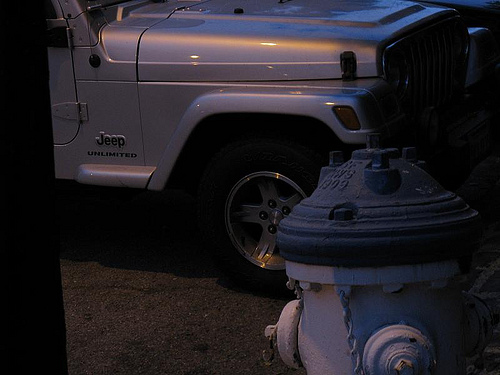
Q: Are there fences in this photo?
A: No, there are no fences.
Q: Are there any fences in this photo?
A: No, there are no fences.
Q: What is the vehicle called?
A: The vehicle is a jeep.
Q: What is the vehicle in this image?
A: The vehicle is a jeep.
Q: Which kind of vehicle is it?
A: The vehicle is a jeep.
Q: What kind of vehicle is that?
A: That is a jeep.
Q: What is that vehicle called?
A: That is a jeep.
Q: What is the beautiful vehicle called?
A: The vehicle is a jeep.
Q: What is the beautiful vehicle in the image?
A: The vehicle is a jeep.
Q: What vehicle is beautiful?
A: The vehicle is a jeep.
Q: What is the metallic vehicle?
A: The vehicle is a jeep.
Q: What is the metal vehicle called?
A: The vehicle is a jeep.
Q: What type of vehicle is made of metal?
A: The vehicle is a jeep.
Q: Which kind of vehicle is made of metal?
A: The vehicle is a jeep.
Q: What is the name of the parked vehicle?
A: The vehicle is a jeep.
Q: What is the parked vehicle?
A: The vehicle is a jeep.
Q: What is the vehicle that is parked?
A: The vehicle is a jeep.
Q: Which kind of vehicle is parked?
A: The vehicle is a jeep.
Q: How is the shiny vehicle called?
A: The vehicle is a jeep.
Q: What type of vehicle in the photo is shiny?
A: The vehicle is a jeep.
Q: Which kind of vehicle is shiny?
A: The vehicle is a jeep.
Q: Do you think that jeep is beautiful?
A: Yes, the jeep is beautiful.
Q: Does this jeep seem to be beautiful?
A: Yes, the jeep is beautiful.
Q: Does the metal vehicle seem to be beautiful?
A: Yes, the jeep is beautiful.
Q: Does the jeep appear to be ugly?
A: No, the jeep is beautiful.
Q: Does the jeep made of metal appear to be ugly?
A: No, the jeep is beautiful.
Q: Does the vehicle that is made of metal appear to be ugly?
A: No, the jeep is beautiful.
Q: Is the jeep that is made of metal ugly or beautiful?
A: The jeep is beautiful.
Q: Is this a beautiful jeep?
A: Yes, this is a beautiful jeep.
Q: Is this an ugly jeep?
A: No, this is a beautiful jeep.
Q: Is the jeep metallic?
A: Yes, the jeep is metallic.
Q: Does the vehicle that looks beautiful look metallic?
A: Yes, the jeep is metallic.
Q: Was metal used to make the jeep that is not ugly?
A: Yes, the jeep is made of metal.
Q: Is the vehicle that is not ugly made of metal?
A: Yes, the jeep is made of metal.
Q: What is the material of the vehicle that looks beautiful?
A: The jeep is made of metal.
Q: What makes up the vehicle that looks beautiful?
A: The jeep is made of metal.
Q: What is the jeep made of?
A: The jeep is made of metal.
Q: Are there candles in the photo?
A: No, there are no candles.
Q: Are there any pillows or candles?
A: No, there are no candles or pillows.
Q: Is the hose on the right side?
A: Yes, the hose is on the right of the image.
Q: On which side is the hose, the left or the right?
A: The hose is on the right of the image.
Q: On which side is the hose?
A: The hose is on the right of the image.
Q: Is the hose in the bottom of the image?
A: Yes, the hose is in the bottom of the image.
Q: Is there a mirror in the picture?
A: Yes, there is a mirror.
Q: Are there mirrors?
A: Yes, there is a mirror.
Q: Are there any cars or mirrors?
A: Yes, there is a mirror.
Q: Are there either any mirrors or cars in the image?
A: Yes, there is a mirror.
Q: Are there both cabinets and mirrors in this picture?
A: No, there is a mirror but no cabinets.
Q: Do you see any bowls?
A: No, there are no bowls.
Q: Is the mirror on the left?
A: Yes, the mirror is on the left of the image.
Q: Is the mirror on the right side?
A: No, the mirror is on the left of the image.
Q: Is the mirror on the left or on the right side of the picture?
A: The mirror is on the left of the image.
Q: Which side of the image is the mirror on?
A: The mirror is on the left of the image.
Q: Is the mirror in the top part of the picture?
A: Yes, the mirror is in the top of the image.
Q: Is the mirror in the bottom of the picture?
A: No, the mirror is in the top of the image.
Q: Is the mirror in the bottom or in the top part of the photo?
A: The mirror is in the top of the image.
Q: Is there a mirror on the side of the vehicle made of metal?
A: Yes, there is a mirror on the side of the jeep.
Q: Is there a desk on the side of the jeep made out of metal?
A: No, there is a mirror on the side of the jeep.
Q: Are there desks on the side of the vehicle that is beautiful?
A: No, there is a mirror on the side of the jeep.